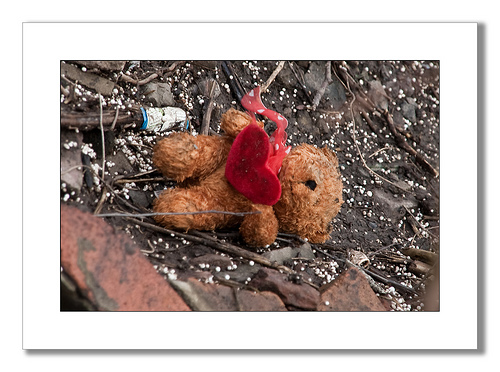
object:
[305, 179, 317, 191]
nose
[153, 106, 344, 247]
bear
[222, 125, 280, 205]
heart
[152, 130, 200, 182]
leg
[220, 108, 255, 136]
arm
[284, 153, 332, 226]
face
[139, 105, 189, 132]
can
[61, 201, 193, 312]
brick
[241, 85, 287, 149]
ribbon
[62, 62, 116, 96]
wood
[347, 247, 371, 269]
trash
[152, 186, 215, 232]
right leg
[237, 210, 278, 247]
left arm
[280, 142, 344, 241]
head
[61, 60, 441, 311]
ground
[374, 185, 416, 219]
rock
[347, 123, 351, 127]
pieces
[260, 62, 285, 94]
branches